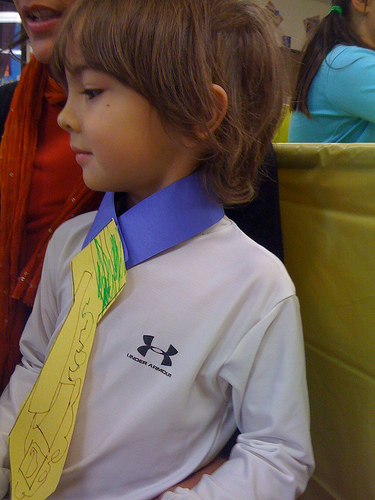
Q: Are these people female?
A: No, they are both male and female.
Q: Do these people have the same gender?
A: No, they are both male and female.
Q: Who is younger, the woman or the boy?
A: The boy is younger than the woman.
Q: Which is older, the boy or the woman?
A: The woman is older than the boy.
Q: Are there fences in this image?
A: No, there are no fences.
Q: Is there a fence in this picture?
A: No, there are no fences.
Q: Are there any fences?
A: No, there are no fences.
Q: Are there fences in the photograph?
A: No, there are no fences.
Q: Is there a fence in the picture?
A: No, there are no fences.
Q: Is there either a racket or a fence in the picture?
A: No, there are no fences or rackets.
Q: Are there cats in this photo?
A: No, there are no cats.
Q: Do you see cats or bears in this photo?
A: No, there are no cats or bears.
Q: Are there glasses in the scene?
A: No, there are no glasses.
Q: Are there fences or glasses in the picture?
A: No, there are no glasses or fences.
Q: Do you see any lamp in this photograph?
A: No, there are no lamps.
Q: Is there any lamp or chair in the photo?
A: No, there are no lamps or chairs.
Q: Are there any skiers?
A: No, there are no skiers.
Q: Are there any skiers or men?
A: No, there are no skiers or men.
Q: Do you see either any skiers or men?
A: No, there are no skiers or men.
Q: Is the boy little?
A: Yes, the boy is little.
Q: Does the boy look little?
A: Yes, the boy is little.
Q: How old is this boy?
A: The boy is little.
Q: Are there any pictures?
A: No, there are no pictures.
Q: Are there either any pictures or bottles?
A: No, there are no pictures or bottles.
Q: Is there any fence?
A: No, there are no fences.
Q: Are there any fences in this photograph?
A: No, there are no fences.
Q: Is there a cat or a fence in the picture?
A: No, there are no fences or cats.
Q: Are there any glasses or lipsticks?
A: No, there are no glasses or lipsticks.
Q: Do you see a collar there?
A: Yes, there is a collar.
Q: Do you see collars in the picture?
A: Yes, there is a collar.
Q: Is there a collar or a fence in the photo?
A: Yes, there is a collar.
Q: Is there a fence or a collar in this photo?
A: Yes, there is a collar.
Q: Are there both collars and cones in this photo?
A: No, there is a collar but no cones.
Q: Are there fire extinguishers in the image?
A: No, there are no fire extinguishers.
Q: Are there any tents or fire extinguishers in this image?
A: No, there are no fire extinguishers or tents.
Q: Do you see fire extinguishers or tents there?
A: No, there are no fire extinguishers or tents.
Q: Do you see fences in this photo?
A: No, there are no fences.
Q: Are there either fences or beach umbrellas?
A: No, there are no fences or beach umbrellas.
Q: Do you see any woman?
A: Yes, there is a woman.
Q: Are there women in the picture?
A: Yes, there is a woman.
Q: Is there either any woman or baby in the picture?
A: Yes, there is a woman.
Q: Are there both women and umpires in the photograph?
A: No, there is a woman but no umpires.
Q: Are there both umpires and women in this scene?
A: No, there is a woman but no umpires.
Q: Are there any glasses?
A: No, there are no glasses.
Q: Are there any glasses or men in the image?
A: No, there are no glasses or men.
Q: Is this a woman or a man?
A: This is a woman.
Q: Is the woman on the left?
A: Yes, the woman is on the left of the image.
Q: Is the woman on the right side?
A: No, the woman is on the left of the image.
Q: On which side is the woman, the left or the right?
A: The woman is on the left of the image.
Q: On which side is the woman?
A: The woman is on the left of the image.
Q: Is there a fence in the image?
A: No, there are no fences.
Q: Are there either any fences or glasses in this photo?
A: No, there are no fences or glasses.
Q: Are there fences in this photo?
A: No, there are no fences.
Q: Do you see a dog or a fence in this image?
A: No, there are no fences or dogs.